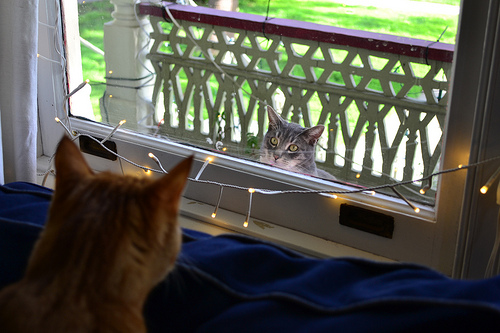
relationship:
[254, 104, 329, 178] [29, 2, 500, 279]
cat near window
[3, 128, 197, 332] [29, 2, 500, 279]
cat near window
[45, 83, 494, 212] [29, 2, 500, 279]
lights across window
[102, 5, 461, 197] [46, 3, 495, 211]
railing on patio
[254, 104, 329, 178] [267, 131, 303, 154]
cat has eyes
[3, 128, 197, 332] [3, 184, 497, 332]
cat on blanket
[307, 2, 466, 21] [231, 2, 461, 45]
sun on grass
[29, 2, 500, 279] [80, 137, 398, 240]
window has handles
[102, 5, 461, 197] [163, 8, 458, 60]
railing has border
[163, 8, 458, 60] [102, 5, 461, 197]
border on top of railing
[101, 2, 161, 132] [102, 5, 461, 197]
pillar at end of railing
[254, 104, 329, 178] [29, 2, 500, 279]
cat looking in window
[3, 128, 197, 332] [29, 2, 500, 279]
cat looking out of window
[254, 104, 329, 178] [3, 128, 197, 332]
cat looking at cat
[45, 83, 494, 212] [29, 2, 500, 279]
lights strung across window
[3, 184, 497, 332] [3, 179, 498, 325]
blanket on back of couch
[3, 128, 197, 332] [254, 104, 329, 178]
cat looking at cat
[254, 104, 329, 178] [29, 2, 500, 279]
cat outside of window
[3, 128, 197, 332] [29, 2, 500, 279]
cat inside of window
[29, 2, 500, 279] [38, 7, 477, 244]
window has frame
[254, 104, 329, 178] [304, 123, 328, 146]
cat has ear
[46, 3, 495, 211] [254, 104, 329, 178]
patio behind cat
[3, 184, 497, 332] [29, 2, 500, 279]
blanket behind window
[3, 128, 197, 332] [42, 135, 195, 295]
cat has head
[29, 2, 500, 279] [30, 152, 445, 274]
window has edge